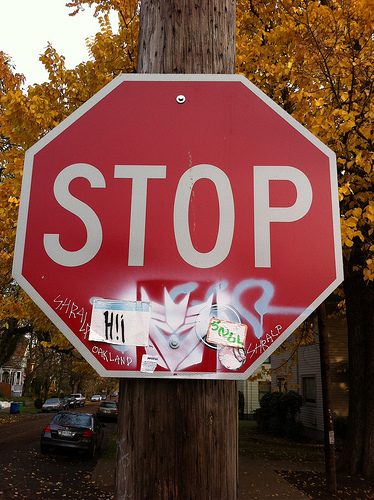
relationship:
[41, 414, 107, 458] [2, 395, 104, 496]
black car parked on street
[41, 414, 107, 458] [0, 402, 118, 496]
black car parked on road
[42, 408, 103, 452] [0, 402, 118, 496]
black car parked on road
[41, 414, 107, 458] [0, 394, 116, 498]
black car parked on road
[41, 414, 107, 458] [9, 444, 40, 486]
black car parked on road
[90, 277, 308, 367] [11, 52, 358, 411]
graffiti on sign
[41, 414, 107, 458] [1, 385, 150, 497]
black car along road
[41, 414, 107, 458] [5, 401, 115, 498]
black car parked on street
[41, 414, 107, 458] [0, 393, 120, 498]
black car parked on street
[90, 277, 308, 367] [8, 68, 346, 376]
graffiti painted on sign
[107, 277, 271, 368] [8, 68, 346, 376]
graffiti painted on sign